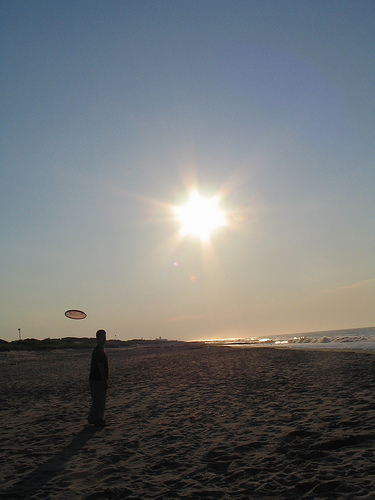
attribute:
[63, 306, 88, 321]
frisbee — on air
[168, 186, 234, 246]
sun — bright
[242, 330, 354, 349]
waves — strong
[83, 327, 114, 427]
man — throwing a frisbee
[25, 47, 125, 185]
sky — clear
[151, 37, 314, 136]
sky — blue 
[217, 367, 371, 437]
sand — brown